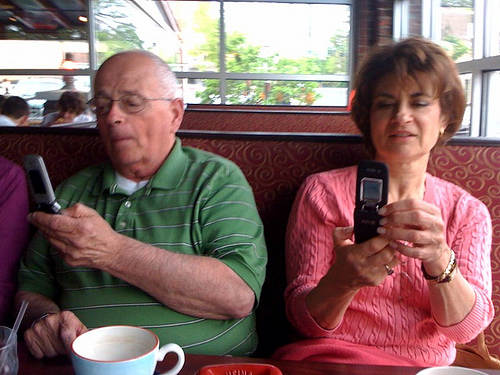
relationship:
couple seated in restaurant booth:
[97, 64, 480, 154] [19, 119, 498, 357]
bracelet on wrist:
[420, 249, 458, 285] [421, 240, 464, 311]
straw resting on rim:
[4, 300, 36, 338] [0, 321, 32, 361]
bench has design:
[2, 127, 497, 369] [450, 146, 497, 190]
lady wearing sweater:
[290, 40, 492, 362] [285, 166, 497, 369]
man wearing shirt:
[11, 49, 270, 359] [54, 150, 264, 360]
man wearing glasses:
[46, 49, 269, 359] [80, 85, 173, 106]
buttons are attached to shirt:
[111, 196, 140, 232] [43, 155, 269, 346]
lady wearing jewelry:
[290, 40, 492, 362] [380, 250, 457, 280]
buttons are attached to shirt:
[113, 194, 138, 226] [54, 150, 264, 360]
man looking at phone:
[11, 49, 270, 359] [23, 147, 83, 269]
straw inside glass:
[4, 300, 36, 338] [1, 298, 37, 370]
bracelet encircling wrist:
[424, 246, 459, 289] [428, 245, 468, 288]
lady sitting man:
[275, 33, 491, 361] [46, 49, 269, 359]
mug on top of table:
[67, 322, 179, 372] [24, 335, 437, 373]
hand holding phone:
[30, 197, 120, 274] [22, 155, 60, 217]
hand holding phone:
[377, 198, 447, 261] [351, 159, 390, 245]